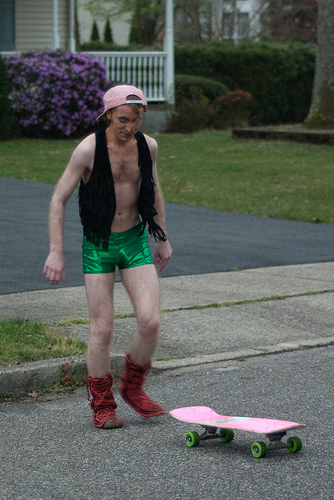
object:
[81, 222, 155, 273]
shorts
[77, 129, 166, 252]
vest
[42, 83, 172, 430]
man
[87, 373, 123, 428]
boot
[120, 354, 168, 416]
boot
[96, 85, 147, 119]
hat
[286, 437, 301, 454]
front wheel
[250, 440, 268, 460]
front wheel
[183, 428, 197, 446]
back wheel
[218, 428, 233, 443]
back wheel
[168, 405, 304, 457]
skateboard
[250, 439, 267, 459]
wheel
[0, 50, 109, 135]
flower bush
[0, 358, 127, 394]
curb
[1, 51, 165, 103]
porch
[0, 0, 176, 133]
house